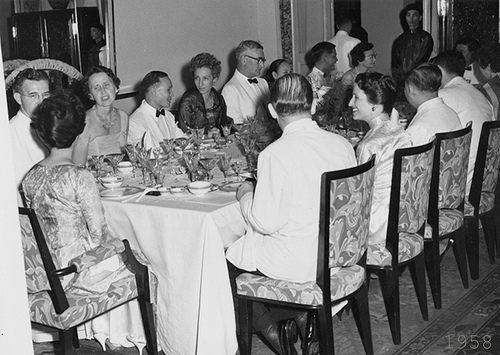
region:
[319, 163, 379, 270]
decorative pattern on high back of chair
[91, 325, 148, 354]
pointed backs of a pair of woman's stilettos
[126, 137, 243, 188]
many low, goblet style glass on a table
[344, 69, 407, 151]
profile of a seated woman smiling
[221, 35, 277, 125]
man wearing black bow tie and white jacket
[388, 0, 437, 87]
dinner attendant waiting to assist people having dinner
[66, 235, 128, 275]
padded right armrest of dinner chair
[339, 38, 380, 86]
short-haired woman wearing eyeglasses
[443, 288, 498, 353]
flat decorative rug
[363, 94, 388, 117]
woman's left ear with ear ring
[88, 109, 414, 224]
A large dining table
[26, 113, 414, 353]
A large white tablecloth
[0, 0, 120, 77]
A mirror on the wall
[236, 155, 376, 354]
A wooden chair with a floral pattern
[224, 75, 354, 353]
A man in a white suit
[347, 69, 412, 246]
A dark haired woman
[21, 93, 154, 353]
A dark haired woman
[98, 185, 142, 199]
A plate on the table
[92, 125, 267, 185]
drinking glasses on the table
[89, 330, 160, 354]
A pair of high heel shoes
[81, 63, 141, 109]
Person has short dark hair.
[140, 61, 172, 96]
Person has short dark hair.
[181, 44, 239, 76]
Person has wavy short hair.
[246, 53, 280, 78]
Glasses on person's face.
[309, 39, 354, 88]
Person has short dark hair.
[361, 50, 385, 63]
Glasses on person's face.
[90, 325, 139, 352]
Woman wearing heels on feet.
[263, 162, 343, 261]
Person wearing white jacket.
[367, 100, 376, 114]
Earrings on woman's ear.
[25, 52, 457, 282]
Many people sitting around table.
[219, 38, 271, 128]
Man wearing black bow tie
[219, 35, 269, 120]
Man wearing white suit jacket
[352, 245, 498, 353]
Floral rug behind chair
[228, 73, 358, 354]
Man wearing white suit jacket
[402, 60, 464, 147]
Man wearing white suit jacket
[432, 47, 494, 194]
Man wearing white suit jacket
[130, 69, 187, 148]
Man wearing white suit jacket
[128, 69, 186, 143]
Man wearing black bow tie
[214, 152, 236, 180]
Crystal glass in front of man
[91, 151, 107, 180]
Crystal glass in front of man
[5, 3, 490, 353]
people sits around a table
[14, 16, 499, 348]
people is eating on a table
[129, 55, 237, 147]
a man and a woman are talking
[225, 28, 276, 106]
old man wears glasses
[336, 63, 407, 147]
a woman is smiling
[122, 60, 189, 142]
man wears a white shirt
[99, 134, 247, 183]
glasses of wine on a table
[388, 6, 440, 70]
man stands on side the table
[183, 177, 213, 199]
a small white bowl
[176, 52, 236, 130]
woman has short hair